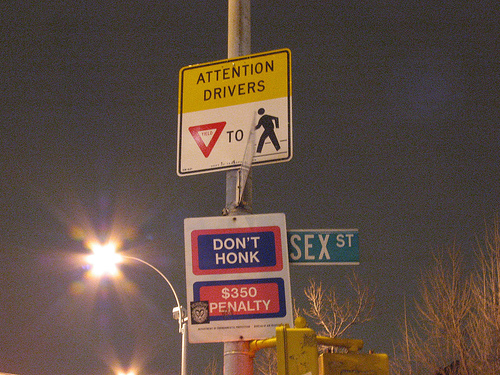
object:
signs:
[174, 48, 312, 344]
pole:
[222, 0, 256, 375]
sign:
[288, 227, 361, 266]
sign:
[183, 212, 293, 344]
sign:
[174, 48, 294, 180]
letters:
[193, 60, 274, 101]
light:
[83, 242, 125, 281]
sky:
[0, 1, 500, 375]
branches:
[290, 236, 500, 375]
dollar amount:
[222, 286, 258, 300]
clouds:
[248, 0, 500, 230]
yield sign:
[188, 121, 227, 158]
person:
[252, 107, 281, 153]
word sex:
[290, 233, 331, 261]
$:
[222, 287, 232, 300]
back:
[291, 280, 500, 375]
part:
[306, 279, 322, 302]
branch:
[285, 277, 377, 338]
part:
[242, 56, 287, 158]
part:
[95, 251, 107, 269]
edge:
[243, 0, 252, 56]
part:
[129, 1, 184, 57]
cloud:
[1, 1, 177, 201]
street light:
[80, 254, 189, 375]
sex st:
[290, 233, 355, 261]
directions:
[211, 236, 261, 264]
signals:
[251, 320, 390, 375]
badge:
[190, 301, 209, 324]